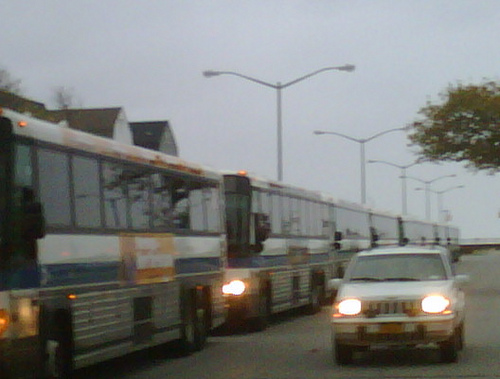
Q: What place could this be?
A: It is a road.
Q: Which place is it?
A: It is a road.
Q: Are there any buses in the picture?
A: Yes, there is a bus.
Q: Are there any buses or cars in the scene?
A: Yes, there is a bus.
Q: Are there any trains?
A: No, there are no trains.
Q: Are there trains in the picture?
A: No, there are no trains.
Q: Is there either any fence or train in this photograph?
A: No, there are no trains or fences.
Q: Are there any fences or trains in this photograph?
A: No, there are no trains or fences.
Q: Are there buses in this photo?
A: Yes, there is a bus.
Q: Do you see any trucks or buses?
A: Yes, there is a bus.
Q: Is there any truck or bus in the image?
A: Yes, there is a bus.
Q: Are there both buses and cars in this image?
A: Yes, there are both a bus and a car.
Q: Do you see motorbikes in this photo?
A: No, there are no motorbikes.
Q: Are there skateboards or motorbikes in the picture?
A: No, there are no motorbikes or skateboards.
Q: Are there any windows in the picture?
A: Yes, there is a window.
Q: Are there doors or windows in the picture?
A: Yes, there is a window.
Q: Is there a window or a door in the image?
A: Yes, there is a window.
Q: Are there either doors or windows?
A: Yes, there is a window.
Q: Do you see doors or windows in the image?
A: Yes, there is a window.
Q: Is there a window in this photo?
A: Yes, there is a window.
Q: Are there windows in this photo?
A: Yes, there is a window.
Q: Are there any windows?
A: Yes, there is a window.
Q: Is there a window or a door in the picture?
A: Yes, there is a window.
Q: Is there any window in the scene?
A: Yes, there is a window.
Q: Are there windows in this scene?
A: Yes, there is a window.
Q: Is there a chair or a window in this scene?
A: Yes, there is a window.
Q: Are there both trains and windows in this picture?
A: No, there is a window but no trains.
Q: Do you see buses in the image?
A: Yes, there is a bus.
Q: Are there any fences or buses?
A: Yes, there is a bus.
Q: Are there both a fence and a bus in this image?
A: No, there is a bus but no fences.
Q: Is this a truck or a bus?
A: This is a bus.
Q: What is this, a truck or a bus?
A: This is a bus.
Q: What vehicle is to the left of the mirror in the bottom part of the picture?
A: The vehicle is a bus.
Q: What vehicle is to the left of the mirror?
A: The vehicle is a bus.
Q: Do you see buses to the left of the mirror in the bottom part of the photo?
A: Yes, there is a bus to the left of the mirror.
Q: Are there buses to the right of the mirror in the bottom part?
A: No, the bus is to the left of the mirror.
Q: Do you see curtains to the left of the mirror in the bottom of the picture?
A: No, there is a bus to the left of the mirror.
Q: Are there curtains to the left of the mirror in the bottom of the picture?
A: No, there is a bus to the left of the mirror.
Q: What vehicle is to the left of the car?
A: The vehicle is a bus.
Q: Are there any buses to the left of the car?
A: Yes, there is a bus to the left of the car.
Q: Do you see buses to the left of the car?
A: Yes, there is a bus to the left of the car.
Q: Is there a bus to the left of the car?
A: Yes, there is a bus to the left of the car.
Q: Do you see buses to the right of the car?
A: No, the bus is to the left of the car.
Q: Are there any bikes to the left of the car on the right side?
A: No, there is a bus to the left of the car.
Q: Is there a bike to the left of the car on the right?
A: No, there is a bus to the left of the car.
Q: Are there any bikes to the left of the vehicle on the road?
A: No, there is a bus to the left of the car.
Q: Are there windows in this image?
A: Yes, there is a window.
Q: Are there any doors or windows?
A: Yes, there is a window.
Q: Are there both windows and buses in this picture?
A: Yes, there are both a window and a bus.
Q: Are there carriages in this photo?
A: No, there are no carriages.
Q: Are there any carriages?
A: No, there are no carriages.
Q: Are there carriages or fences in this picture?
A: No, there are no carriages or fences.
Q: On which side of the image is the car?
A: The car is on the right of the image.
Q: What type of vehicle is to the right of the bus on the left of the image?
A: The vehicle is a car.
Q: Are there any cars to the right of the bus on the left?
A: Yes, there is a car to the right of the bus.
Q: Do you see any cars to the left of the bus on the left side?
A: No, the car is to the right of the bus.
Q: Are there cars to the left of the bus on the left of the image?
A: No, the car is to the right of the bus.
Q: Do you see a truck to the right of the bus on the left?
A: No, there is a car to the right of the bus.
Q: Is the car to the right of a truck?
A: No, the car is to the right of a bus.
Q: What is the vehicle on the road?
A: The vehicle is a car.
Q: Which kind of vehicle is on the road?
A: The vehicle is a car.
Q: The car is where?
A: The car is on the road.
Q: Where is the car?
A: The car is on the road.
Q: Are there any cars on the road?
A: Yes, there is a car on the road.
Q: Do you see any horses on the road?
A: No, there is a car on the road.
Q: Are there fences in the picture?
A: No, there are no fences.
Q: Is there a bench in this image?
A: No, there are no benches.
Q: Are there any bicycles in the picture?
A: No, there are no bicycles.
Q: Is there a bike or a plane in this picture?
A: No, there are no bikes or airplanes.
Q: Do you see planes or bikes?
A: No, there are no bikes or planes.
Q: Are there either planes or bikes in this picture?
A: No, there are no bikes or planes.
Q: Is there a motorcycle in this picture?
A: No, there are no motorcycles.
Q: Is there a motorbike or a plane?
A: No, there are no motorcycles or airplanes.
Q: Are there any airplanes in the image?
A: No, there are no airplanes.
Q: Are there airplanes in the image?
A: No, there are no airplanes.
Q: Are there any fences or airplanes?
A: No, there are no airplanes or fences.